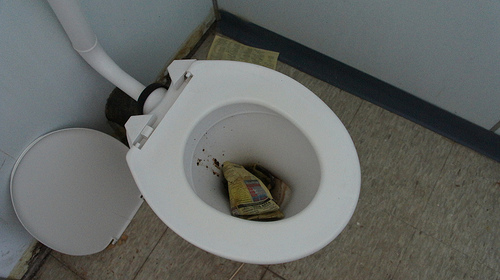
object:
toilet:
[120, 57, 365, 268]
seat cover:
[7, 126, 146, 256]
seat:
[123, 58, 363, 266]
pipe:
[47, 0, 146, 101]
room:
[1, 1, 500, 280]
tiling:
[274, 58, 363, 132]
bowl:
[122, 59, 363, 267]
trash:
[218, 159, 286, 223]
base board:
[209, 7, 500, 162]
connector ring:
[135, 82, 169, 114]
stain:
[195, 156, 201, 167]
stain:
[212, 156, 220, 169]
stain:
[211, 169, 220, 178]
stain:
[202, 147, 212, 158]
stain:
[204, 165, 210, 169]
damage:
[9, 242, 88, 280]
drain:
[223, 165, 271, 200]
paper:
[206, 33, 281, 71]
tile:
[387, 228, 499, 280]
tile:
[414, 142, 500, 272]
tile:
[346, 99, 456, 229]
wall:
[1, 0, 220, 279]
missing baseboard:
[150, 7, 218, 90]